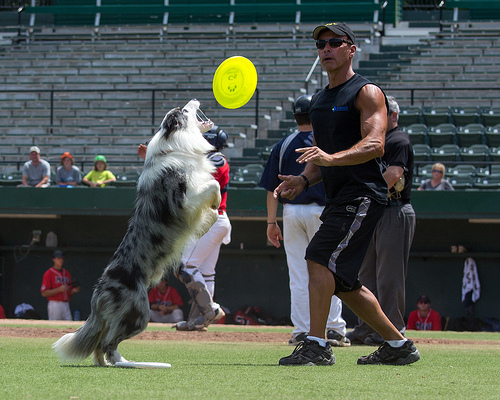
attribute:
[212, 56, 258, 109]
frisbee — yellow, in air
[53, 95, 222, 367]
dog — leaping, grey, black, white, on hind legs, large, fluffy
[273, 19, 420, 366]
man — standing, muscular, athletic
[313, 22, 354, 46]
hat — black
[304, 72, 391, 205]
shirt — black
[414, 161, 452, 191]
person — sitting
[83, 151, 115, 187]
person — sitting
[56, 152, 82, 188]
person — sitting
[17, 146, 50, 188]
person — sitting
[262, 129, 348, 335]
baseball uniform — blue, white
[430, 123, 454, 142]
seat — empty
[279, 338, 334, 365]
shoe — black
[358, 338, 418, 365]
shoe — black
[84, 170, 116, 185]
shirt — yellow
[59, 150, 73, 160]
hat — orange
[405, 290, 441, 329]
person — sitting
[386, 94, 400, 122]
hair — grey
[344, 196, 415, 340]
slacks — grey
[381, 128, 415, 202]
shirt — black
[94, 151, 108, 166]
hat — green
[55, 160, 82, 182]
shirt — grey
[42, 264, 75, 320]
baseball outfit — red, white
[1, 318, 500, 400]
field — green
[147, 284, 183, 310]
shirt — red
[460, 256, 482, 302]
towel — hung